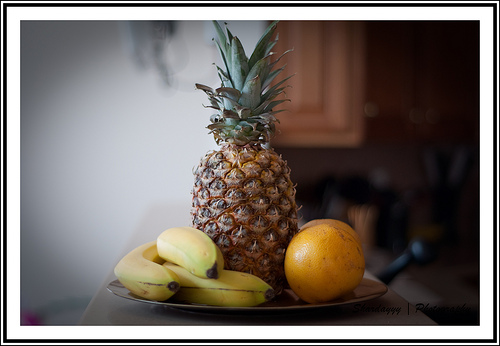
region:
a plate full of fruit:
[105, 20, 387, 310]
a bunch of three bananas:
[113, 225, 275, 307]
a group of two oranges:
[284, 216, 364, 304]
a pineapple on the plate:
[190, 20, 299, 291]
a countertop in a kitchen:
[75, 204, 437, 324]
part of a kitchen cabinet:
[264, 21, 364, 146]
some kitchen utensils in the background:
[407, 143, 479, 239]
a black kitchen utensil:
[375, 235, 432, 285]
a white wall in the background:
[20, 19, 265, 325]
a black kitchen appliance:
[292, 167, 402, 255]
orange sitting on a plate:
[284, 220, 356, 304]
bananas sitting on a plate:
[119, 231, 255, 323]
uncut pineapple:
[179, 31, 316, 284]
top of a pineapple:
[185, 20, 291, 142]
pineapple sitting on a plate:
[190, 38, 290, 300]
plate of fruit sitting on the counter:
[116, 32, 346, 332]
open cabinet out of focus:
[276, 32, 406, 162]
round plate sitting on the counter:
[290, 291, 396, 316]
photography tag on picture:
[330, 296, 478, 317]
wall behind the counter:
[68, 122, 165, 193]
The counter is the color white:
[83, 300, 438, 322]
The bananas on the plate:
[117, 223, 277, 304]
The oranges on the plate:
[281, 200, 368, 308]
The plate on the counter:
[101, 238, 412, 323]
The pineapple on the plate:
[188, 26, 300, 300]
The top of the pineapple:
[191, 19, 298, 149]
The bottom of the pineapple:
[183, 148, 306, 304]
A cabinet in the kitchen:
[256, 26, 378, 152]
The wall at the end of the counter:
[31, 32, 197, 220]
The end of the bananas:
[164, 260, 277, 304]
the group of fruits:
[115, 19, 364, 304]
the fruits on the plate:
[106, 19, 389, 312]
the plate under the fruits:
[108, 278, 388, 313]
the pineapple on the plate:
[190, 21, 300, 300]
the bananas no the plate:
[113, 225, 275, 307]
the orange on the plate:
[284, 222, 364, 302]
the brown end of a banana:
[166, 280, 179, 291]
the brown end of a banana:
[204, 263, 218, 280]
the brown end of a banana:
[263, 288, 274, 300]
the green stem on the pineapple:
[196, 20, 293, 141]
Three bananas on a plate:
[110, 224, 276, 316]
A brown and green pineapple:
[192, 22, 300, 292]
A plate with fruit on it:
[106, 20, 391, 320]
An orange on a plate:
[279, 221, 370, 310]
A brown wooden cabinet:
[265, 24, 365, 149]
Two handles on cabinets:
[401, 101, 442, 132]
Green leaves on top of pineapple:
[203, 19, 290, 164]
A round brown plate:
[107, 266, 388, 320]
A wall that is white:
[21, 23, 261, 319]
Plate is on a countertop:
[77, 258, 438, 323]